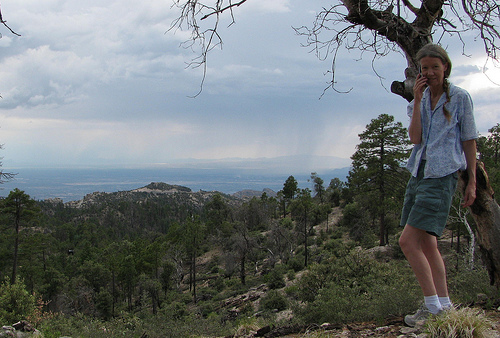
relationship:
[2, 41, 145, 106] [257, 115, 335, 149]
cloud in sky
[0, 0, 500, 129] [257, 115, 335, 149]
cloud in sky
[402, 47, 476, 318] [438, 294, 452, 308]
woman has on white sock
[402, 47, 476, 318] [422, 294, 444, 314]
woman has on sock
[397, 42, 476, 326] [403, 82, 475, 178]
woman has on blue shirt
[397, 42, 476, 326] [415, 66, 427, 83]
woman on a cell phone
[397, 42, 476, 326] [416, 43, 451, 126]
woman has hair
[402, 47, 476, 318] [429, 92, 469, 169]
woman has blue shirt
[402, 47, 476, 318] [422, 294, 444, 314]
woman has sock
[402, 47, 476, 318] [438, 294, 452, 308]
woman has white sock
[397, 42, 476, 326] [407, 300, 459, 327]
woman has grey shoes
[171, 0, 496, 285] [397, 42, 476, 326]
tree behind woman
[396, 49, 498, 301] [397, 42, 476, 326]
trunk behind woman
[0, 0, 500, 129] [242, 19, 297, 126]
cloud in sky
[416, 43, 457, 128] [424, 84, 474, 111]
hair over shoulder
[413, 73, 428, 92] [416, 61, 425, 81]
fingers on cell phone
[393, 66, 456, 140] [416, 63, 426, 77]
hand holding holding cell phone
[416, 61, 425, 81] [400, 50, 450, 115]
cell phone lifted up to face